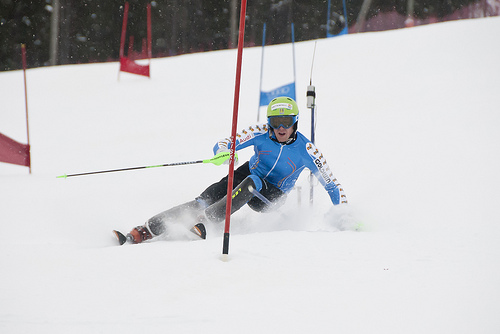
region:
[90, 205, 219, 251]
Man on skis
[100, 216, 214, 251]
Man is on skis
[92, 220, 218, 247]
Man riding skis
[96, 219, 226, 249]
Man is riding skis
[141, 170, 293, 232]
Man wearing pants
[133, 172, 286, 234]
Man is wearing pants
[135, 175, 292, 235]
Man wearing black pants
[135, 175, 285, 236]
Man is wearing black pants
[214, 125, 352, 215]
Man is wearing a blue jacket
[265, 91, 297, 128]
Man is wearing a green helmet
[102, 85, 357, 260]
a skier on a hill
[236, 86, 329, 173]
skier wears a green helmet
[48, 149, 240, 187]
a green and gray pole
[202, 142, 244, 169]
handle of pole is green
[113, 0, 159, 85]
a red signs on snow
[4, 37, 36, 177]
a red signs on snow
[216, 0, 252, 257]
a red pole in front of skier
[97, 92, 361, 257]
skier wears blue coat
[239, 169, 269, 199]
knee has a blue band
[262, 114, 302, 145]
goggles in front eyes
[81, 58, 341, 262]
the person is skiing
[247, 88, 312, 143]
the helmet is lime-green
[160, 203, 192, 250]
the snow being kicked into the air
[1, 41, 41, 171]
the red flag on the course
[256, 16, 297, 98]
the blue flag on the course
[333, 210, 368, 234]
the hand in the snow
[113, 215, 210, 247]
the skies on the ground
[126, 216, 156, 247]
the red boot on the mans foot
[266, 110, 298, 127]
the blue googles on the mans face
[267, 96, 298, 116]
the green helmet on the head of the man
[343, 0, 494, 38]
the red mesh fence on the hill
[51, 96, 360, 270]
the skiier on the slope course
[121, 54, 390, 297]
Man skiing in the snow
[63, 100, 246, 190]
Ski pole in man's hand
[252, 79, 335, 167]
Man wearing a helmet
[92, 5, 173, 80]
Wall in between the ski path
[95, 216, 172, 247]
Man wearing ski shoes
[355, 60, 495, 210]
The snow is smooth and white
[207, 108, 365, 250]
Man wearing long sleeves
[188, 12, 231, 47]
Snow falling in the background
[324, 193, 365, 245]
Mans hand is in the snow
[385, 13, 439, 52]
Top of hill in background